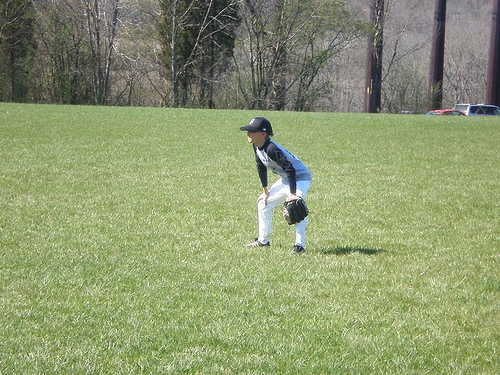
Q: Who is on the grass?
A: The boy.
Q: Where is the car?
A: In the distance.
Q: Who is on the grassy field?
A: The boy.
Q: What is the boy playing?
A: Baseball.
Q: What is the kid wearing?
A: A baseball uniform.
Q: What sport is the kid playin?
A: Baseball.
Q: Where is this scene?
A: A large field.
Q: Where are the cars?
A: In front of the trees.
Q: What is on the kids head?
A: A baseball cap.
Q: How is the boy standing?
A: He is crouching.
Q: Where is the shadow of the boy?
A: Behind him.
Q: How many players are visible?
A: One.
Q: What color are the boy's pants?
A: White.